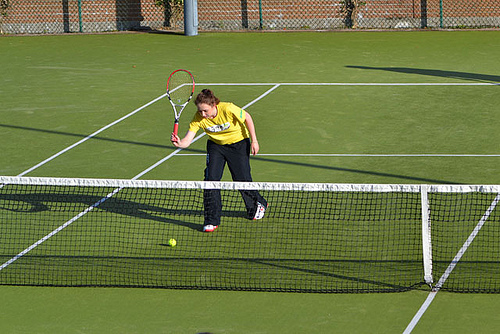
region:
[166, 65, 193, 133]
a red, white, and black tennis racket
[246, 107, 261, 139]
an arm of a person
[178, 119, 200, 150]
an arm of a person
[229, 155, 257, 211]
the leg of a person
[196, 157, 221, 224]
the leg of a person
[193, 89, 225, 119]
the head of a person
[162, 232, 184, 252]
a yellow tennis ball on the ground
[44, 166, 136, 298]
a tennis net on a tennis court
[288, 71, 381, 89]
white line of a tennis court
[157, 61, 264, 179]
a woman with a tennis racket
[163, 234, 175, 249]
A ball on ground.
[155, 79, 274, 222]
A girl playing tennis.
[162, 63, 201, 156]
A red and white tennis racket.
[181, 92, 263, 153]
A girl wearing a yellow shirt.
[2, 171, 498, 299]
A black and white net.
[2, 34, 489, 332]
A green tennis court.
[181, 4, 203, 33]
A gray metal pole.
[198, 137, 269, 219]
Black pants on girl.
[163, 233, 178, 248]
A bright green tennis ball.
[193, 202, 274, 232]
White tennis shoes.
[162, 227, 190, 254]
A tennis ball behind the net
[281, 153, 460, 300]
A net setup on a tennis court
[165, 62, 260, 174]
A woman holding a tennis racket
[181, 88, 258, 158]
A woman wearing a yellow t-shirt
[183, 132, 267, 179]
A woman wearing black pants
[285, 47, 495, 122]
Baseline on a tennis court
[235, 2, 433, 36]
A brick wall behind a chain link fence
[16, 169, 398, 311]
A white and black net on a tennis cort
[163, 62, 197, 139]
A red, white and black tennis racket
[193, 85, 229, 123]
A woman with brown hair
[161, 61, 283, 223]
the woman holding a tennis racket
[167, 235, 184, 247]
the tennis ball on the ground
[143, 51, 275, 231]
the woman playing tennis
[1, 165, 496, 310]
the tennis net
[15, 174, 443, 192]
the trim on the net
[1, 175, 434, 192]
the trim is white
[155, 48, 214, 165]
the tennis racket is black white and red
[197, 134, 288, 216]
the woman wearing black pants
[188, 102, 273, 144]
the woman wearing a yellow t shirt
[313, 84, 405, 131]
the court is green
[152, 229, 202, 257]
bright green tennis ball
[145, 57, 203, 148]
orange and white racket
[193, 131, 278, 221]
plain black jogging pants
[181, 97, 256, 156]
yellow tee with logo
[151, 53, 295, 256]
woman holding tennis racket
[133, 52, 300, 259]
woman bending for tennis ball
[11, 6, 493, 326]
girl on tennis court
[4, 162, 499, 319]
white tennis net on green court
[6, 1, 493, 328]
person playing on tennis court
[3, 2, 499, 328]
green grass tennis court